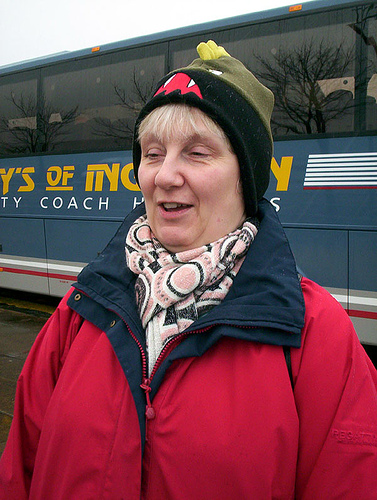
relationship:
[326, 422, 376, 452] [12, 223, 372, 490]
logo attached to coat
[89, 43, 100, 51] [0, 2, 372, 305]
light on bus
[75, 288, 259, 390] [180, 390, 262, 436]
zipper on coat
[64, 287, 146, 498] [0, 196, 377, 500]
edge lining coat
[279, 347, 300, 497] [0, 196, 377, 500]
edge lining coat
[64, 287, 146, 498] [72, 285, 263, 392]
edge partially covering zipper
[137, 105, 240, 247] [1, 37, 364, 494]
face belonging to woman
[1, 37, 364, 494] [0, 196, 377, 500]
woman wearing coat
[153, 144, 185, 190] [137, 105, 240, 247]
nose attached to face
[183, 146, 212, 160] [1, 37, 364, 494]
left eye belonging to woman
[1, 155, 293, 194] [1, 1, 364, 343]
company name painted on bus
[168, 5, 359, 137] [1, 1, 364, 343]
window built into bus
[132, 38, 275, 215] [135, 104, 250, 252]
cap worn on head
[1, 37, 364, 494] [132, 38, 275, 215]
woman wearing cap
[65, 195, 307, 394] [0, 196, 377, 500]
collar adorning coat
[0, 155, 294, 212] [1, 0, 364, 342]
company logo painted on side of passenger bus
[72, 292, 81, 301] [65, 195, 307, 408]
snap sewn into collar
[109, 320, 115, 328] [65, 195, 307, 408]
button sewn into collar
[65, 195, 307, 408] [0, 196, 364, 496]
collar adorning coat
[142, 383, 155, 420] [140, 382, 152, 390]
pool string attached to zipper handle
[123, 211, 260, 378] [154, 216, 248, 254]
scarf worn around neck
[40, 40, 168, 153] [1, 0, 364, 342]
window built into passenger bus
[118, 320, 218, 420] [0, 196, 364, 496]
zipper on coat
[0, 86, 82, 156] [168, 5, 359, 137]
tree reflection in window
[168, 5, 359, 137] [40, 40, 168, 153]
window in window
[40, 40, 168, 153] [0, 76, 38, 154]
window in window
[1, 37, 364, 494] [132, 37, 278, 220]
woman wearing cap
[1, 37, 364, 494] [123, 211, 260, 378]
woman wearing scarf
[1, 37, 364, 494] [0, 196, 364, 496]
woman wearing coat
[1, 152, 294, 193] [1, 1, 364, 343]
letters on bus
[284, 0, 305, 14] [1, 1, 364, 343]
light on bus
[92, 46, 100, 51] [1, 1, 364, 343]
light on bus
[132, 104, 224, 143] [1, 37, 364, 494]
hair on woman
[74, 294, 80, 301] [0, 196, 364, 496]
snap on coat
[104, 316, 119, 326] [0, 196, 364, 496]
button on coat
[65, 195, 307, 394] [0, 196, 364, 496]
collar on coat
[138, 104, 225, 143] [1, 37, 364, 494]
hair on woman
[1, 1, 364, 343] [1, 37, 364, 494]
bus behind woman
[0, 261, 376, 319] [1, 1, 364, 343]
stripe on bus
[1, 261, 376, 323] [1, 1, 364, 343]
stripe on bus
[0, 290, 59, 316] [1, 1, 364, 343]
line on bus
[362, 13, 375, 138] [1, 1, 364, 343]
window on bus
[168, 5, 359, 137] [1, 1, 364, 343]
window on bus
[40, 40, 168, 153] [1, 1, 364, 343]
window on bus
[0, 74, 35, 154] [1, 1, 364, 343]
window on bus